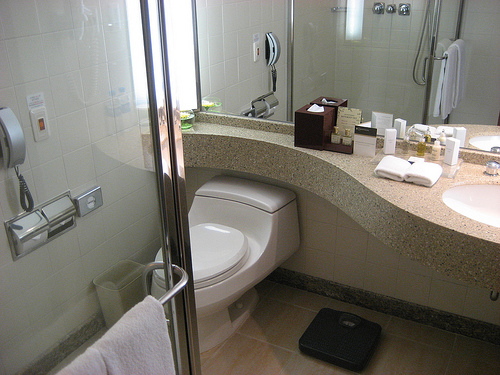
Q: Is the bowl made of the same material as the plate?
A: Yes, both the bowl and the plate are made of glass.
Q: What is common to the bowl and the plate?
A: The material, both the bowl and the plate are glass.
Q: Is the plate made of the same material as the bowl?
A: Yes, both the plate and the bowl are made of glass.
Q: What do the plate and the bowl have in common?
A: The material, both the plate and the bowl are glass.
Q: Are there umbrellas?
A: No, there are no umbrellas.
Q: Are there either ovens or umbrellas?
A: No, there are no umbrellas or ovens.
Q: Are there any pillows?
A: No, there are no pillows.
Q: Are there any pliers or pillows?
A: No, there are no pillows or pliers.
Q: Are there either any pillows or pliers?
A: No, there are no pillows or pliers.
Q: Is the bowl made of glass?
A: Yes, the bowl is made of glass.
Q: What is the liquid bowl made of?
A: The bowl is made of glass.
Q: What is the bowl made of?
A: The bowl is made of glass.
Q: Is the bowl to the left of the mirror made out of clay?
A: No, the bowl is made of glass.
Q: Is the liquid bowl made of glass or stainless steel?
A: The bowl is made of glass.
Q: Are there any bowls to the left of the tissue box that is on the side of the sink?
A: Yes, there is a bowl to the left of the tissue box.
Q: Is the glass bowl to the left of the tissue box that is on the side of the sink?
A: Yes, the bowl is to the left of the tissue box.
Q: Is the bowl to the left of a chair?
A: No, the bowl is to the left of the tissue box.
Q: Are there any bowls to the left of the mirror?
A: Yes, there is a bowl to the left of the mirror.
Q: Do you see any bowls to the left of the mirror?
A: Yes, there is a bowl to the left of the mirror.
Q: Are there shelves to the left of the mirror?
A: No, there is a bowl to the left of the mirror.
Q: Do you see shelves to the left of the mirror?
A: No, there is a bowl to the left of the mirror.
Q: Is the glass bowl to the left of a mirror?
A: Yes, the bowl is to the left of a mirror.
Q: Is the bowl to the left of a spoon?
A: No, the bowl is to the left of a mirror.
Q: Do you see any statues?
A: No, there are no statues.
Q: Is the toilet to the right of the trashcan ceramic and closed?
A: Yes, the toilet is ceramic and closed.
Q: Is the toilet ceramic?
A: Yes, the toilet is ceramic.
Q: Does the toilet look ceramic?
A: Yes, the toilet is ceramic.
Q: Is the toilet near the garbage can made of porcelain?
A: Yes, the toilet is made of porcelain.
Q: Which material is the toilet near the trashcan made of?
A: The toilet is made of porcelain.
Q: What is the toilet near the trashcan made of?
A: The toilet is made of porcelain.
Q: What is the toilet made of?
A: The toilet is made of porcelain.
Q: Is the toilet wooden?
A: No, the toilet is ceramic.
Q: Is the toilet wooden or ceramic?
A: The toilet is ceramic.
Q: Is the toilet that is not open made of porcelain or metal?
A: The toilet is made of porcelain.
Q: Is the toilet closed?
A: Yes, the toilet is closed.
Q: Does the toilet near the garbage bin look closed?
A: Yes, the toilet is closed.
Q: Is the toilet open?
A: No, the toilet is closed.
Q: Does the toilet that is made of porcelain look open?
A: No, the toilet is closed.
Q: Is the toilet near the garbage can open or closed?
A: The toilet is closed.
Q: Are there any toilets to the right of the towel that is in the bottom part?
A: Yes, there is a toilet to the right of the towel.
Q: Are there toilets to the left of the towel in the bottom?
A: No, the toilet is to the right of the towel.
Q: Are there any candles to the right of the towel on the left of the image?
A: No, there is a toilet to the right of the towel.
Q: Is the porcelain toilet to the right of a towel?
A: Yes, the toilet is to the right of a towel.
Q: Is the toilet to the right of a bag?
A: No, the toilet is to the right of a towel.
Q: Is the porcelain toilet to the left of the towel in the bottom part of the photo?
A: No, the toilet is to the right of the towel.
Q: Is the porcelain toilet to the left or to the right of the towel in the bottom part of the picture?
A: The toilet is to the right of the towel.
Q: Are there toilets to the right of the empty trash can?
A: Yes, there is a toilet to the right of the garbage bin.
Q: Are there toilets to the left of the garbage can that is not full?
A: No, the toilet is to the right of the garbage bin.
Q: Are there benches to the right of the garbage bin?
A: No, there is a toilet to the right of the garbage bin.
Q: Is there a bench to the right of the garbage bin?
A: No, there is a toilet to the right of the garbage bin.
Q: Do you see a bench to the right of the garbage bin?
A: No, there is a toilet to the right of the garbage bin.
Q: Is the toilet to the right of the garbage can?
A: Yes, the toilet is to the right of the garbage can.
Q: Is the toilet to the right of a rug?
A: No, the toilet is to the right of the garbage can.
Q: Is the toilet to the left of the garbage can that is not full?
A: No, the toilet is to the right of the garbage can.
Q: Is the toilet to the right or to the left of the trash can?
A: The toilet is to the right of the trash can.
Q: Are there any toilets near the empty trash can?
A: Yes, there is a toilet near the trash bin.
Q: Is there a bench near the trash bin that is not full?
A: No, there is a toilet near the trashcan.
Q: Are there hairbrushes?
A: No, there are no hairbrushes.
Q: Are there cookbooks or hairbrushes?
A: No, there are no hairbrushes or cookbooks.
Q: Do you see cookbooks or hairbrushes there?
A: No, there are no hairbrushes or cookbooks.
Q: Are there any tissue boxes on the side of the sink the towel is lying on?
A: Yes, there is a tissue box on the side of the sink.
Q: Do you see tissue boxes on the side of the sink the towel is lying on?
A: Yes, there is a tissue box on the side of the sink.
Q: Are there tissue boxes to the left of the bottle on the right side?
A: Yes, there is a tissue box to the left of the bottle.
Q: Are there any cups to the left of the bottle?
A: No, there is a tissue box to the left of the bottle.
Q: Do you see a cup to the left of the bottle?
A: No, there is a tissue box to the left of the bottle.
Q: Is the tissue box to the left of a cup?
A: No, the tissue box is to the left of the bottle.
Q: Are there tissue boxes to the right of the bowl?
A: Yes, there is a tissue box to the right of the bowl.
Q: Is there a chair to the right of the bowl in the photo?
A: No, there is a tissue box to the right of the bowl.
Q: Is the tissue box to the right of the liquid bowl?
A: Yes, the tissue box is to the right of the bowl.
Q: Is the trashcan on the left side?
A: Yes, the trashcan is on the left of the image.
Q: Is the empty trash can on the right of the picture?
A: No, the garbage bin is on the left of the image.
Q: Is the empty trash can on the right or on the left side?
A: The trash can is on the left of the image.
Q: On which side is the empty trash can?
A: The garbage bin is on the left of the image.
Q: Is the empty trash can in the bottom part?
A: Yes, the trashcan is in the bottom of the image.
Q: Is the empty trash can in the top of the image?
A: No, the garbage can is in the bottom of the image.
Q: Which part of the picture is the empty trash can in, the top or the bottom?
A: The garbage can is in the bottom of the image.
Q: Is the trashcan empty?
A: Yes, the trashcan is empty.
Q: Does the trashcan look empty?
A: Yes, the trashcan is empty.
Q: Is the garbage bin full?
A: No, the garbage bin is empty.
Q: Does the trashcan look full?
A: No, the trashcan is empty.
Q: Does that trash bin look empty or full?
A: The trash bin is empty.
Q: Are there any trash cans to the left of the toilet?
A: Yes, there is a trash can to the left of the toilet.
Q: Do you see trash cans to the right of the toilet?
A: No, the trash can is to the left of the toilet.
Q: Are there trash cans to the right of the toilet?
A: No, the trash can is to the left of the toilet.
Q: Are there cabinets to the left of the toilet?
A: No, there is a trash can to the left of the toilet.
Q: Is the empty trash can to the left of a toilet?
A: Yes, the garbage can is to the left of a toilet.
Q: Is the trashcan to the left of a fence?
A: No, the trashcan is to the left of a toilet.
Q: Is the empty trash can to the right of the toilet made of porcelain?
A: No, the garbage bin is to the left of the toilet.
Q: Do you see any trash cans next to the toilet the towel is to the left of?
A: Yes, there is a trash can next to the toilet.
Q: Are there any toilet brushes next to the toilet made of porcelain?
A: No, there is a trash can next to the toilet.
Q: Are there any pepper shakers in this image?
A: No, there are no pepper shakers.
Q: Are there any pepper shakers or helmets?
A: No, there are no pepper shakers or helmets.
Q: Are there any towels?
A: Yes, there is a towel.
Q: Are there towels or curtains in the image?
A: Yes, there is a towel.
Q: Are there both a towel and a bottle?
A: Yes, there are both a towel and a bottle.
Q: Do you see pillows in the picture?
A: No, there are no pillows.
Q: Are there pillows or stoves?
A: No, there are no pillows or stoves.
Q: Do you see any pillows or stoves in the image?
A: No, there are no pillows or stoves.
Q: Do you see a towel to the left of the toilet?
A: Yes, there is a towel to the left of the toilet.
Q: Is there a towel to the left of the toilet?
A: Yes, there is a towel to the left of the toilet.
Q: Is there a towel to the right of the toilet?
A: No, the towel is to the left of the toilet.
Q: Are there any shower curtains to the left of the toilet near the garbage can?
A: No, there is a towel to the left of the toilet.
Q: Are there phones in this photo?
A: Yes, there is a phone.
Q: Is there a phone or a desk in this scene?
A: Yes, there is a phone.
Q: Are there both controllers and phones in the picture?
A: No, there is a phone but no controllers.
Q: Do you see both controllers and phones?
A: No, there is a phone but no controllers.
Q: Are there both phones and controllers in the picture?
A: No, there is a phone but no controllers.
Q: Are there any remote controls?
A: No, there are no remote controls.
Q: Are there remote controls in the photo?
A: No, there are no remote controls.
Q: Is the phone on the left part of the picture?
A: Yes, the phone is on the left of the image.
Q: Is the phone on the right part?
A: No, the phone is on the left of the image.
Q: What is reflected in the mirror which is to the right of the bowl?
A: The telephone is reflected in the mirror.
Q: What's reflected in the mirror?
A: The telephone is reflected in the mirror.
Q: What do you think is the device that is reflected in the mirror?
A: The device is a phone.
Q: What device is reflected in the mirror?
A: The device is a phone.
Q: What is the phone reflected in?
A: The telephone is reflected in the mirror.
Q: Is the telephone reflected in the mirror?
A: Yes, the telephone is reflected in the mirror.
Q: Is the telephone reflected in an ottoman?
A: No, the telephone is reflected in the mirror.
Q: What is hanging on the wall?
A: The phone is hanging on the wall.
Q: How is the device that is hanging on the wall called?
A: The device is a phone.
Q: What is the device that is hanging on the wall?
A: The device is a phone.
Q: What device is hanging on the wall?
A: The device is a phone.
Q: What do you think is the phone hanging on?
A: The phone is hanging on the wall.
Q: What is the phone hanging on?
A: The phone is hanging on the wall.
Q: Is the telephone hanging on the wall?
A: Yes, the telephone is hanging on the wall.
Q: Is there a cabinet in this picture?
A: No, there are no cabinets.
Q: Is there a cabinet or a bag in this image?
A: No, there are no cabinets or bags.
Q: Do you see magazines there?
A: No, there are no magazines.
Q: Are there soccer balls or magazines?
A: No, there are no magazines or soccer balls.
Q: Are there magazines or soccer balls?
A: No, there are no magazines or soccer balls.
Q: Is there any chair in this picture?
A: No, there are no chairs.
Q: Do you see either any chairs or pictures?
A: No, there are no chairs or pictures.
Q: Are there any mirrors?
A: Yes, there is a mirror.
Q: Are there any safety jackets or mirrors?
A: Yes, there is a mirror.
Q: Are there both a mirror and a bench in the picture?
A: No, there is a mirror but no benches.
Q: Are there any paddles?
A: No, there are no paddles.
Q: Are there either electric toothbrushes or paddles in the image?
A: No, there are no paddles or electric toothbrushes.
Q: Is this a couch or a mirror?
A: This is a mirror.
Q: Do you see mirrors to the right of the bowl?
A: Yes, there is a mirror to the right of the bowl.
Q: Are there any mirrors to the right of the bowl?
A: Yes, there is a mirror to the right of the bowl.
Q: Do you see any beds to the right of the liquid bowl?
A: No, there is a mirror to the right of the bowl.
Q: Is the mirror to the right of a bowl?
A: Yes, the mirror is to the right of a bowl.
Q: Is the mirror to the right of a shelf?
A: No, the mirror is to the right of a bowl.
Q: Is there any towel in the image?
A: Yes, there is a towel.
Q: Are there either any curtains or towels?
A: Yes, there is a towel.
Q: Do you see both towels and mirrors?
A: Yes, there are both a towel and a mirror.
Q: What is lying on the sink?
A: The towel is lying on the sink.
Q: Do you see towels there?
A: Yes, there is a towel.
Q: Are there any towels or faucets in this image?
A: Yes, there is a towel.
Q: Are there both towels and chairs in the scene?
A: No, there is a towel but no chairs.